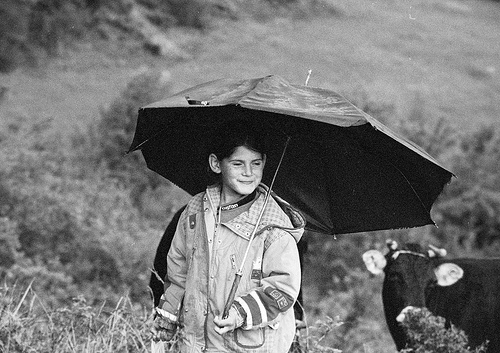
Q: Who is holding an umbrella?
A: The child.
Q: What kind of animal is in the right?
A: Cow.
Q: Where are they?
A: In a pasture.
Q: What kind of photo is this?
A: Black and white.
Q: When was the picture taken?
A: Daytime.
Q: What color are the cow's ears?
A: White.